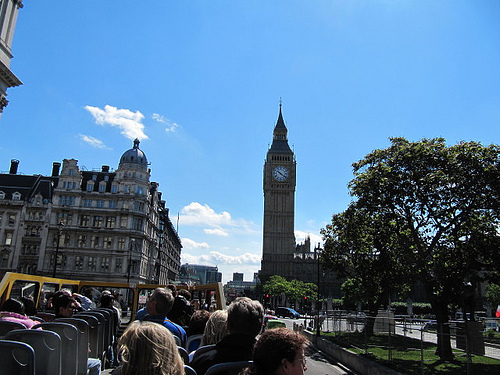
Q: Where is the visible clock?
A: In the tower.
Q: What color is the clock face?
A: White.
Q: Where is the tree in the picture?
A: On the right.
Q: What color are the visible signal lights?
A: Red.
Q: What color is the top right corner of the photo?
A: Blue.